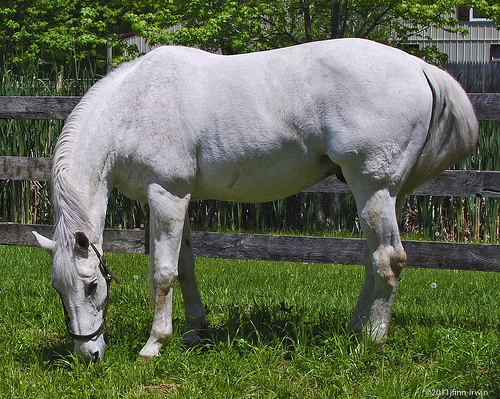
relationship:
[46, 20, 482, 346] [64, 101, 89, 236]
horse has hair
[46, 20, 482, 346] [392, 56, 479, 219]
horse has tail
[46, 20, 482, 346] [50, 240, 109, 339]
horse has face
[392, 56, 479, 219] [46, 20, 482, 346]
tail of horse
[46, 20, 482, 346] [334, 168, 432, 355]
horse has leg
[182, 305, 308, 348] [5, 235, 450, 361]
shadow on ground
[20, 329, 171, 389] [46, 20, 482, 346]
grass under horse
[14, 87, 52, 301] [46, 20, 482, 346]
fence for horse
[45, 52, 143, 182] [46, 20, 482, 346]
mane of horse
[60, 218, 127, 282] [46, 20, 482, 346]
ear of horse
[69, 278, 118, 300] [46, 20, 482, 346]
eye of horse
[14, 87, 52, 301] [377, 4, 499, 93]
fence around building